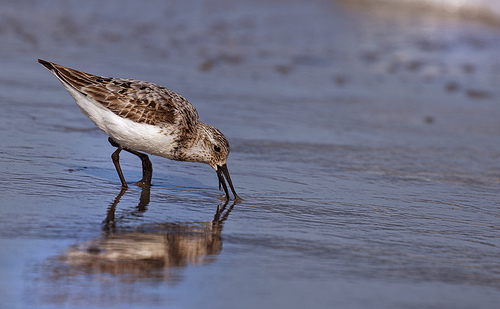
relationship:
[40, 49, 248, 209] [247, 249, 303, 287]
bird in sand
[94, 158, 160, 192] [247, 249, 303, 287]
legs in sand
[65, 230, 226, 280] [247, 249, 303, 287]
reflection in sand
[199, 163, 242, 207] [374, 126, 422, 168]
beek in water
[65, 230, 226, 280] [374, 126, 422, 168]
reflection in water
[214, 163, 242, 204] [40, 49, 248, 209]
beek of bird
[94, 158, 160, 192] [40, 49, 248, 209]
legs of bird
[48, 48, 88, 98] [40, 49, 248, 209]
tail of bird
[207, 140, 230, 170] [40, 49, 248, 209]
eye of bird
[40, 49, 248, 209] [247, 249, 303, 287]
bird on beach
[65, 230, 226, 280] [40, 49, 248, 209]
reflection of bird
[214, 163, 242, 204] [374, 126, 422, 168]
beek in water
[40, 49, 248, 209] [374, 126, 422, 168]
bird in water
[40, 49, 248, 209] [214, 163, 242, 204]
bird using beek